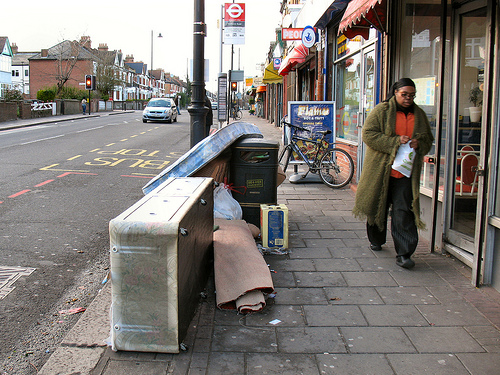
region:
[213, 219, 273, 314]
a rolled up piece of carpet on the sidewalk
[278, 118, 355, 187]
a blue adult bicycle with two tires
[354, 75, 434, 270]
a woman wearing a green coat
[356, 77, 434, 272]
a woman walking down the sidewalk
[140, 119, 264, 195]
an old mattress tossed out to the curb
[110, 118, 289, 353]
a pile of trash stacked on the sidewalk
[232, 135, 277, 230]
a green trash can that needs emptied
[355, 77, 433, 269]
a woman wearing an orange shirt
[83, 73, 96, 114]
a black stoplight with an orange light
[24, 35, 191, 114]
a long row of apartment buildings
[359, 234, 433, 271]
Woman wearing shoes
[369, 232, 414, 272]
Woman is wearing shoes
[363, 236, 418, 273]
Woman wearing black shoes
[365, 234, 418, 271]
Woman is wearing black shoes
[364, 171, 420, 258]
Woman wearing pants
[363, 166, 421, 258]
Woman is wearing pants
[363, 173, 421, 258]
Woman wearing black pants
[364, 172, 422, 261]
Woman is wearing black pants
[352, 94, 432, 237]
Woman wearing a green coat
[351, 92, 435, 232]
Woman is wearing a green coat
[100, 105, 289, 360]
several items are on the sidewalk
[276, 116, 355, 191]
a bicycle is behind the woman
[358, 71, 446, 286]
a woman walks down the sidewalk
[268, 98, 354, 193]
the bicycle is next to the sign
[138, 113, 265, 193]
a mattress lay on top of the pile of items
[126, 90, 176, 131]
a car is in the road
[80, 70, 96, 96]
a traffic light is on the left side of the road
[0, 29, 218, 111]
buildings go all the way down the road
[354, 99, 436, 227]
the woman wears a long green sweater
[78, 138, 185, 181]
the road says BUS STOP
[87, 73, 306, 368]
debris left on the street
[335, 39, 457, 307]
a pedestrian walking down the sidewalk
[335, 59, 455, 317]
a pedestrian walking down a footpath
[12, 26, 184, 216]
an approaching automobile going near a bus stop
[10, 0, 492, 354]
a city street with shops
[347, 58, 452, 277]
a person with a black scarf and orange top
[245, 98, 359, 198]
a bicycle parked on a footpath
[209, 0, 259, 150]
the sign for a bus stop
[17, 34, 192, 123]
a row of townhouses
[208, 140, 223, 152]
the mattress is blue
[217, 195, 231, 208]
the bag is white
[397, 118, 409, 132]
the shirt is orange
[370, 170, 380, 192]
the jacket is olive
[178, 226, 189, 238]
the wheels are black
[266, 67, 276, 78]
the awning is yellow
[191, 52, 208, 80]
the pole is black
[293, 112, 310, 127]
the sign is blue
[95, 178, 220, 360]
A Piece of furniture left out on the curb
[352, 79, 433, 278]
A person walking on the sidewalk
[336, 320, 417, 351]
dark block in the grey sidewalk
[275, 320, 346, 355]
dark block in the grey sidewalk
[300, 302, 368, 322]
dark block in the grey sidewalk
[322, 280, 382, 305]
dark block in the grey sidewalk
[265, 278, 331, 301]
dark block in the grey sidewalk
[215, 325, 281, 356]
dark block in the grey sidewalk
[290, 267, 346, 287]
dark block in the grey sidewalk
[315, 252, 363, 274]
dark block in the grey sidewalk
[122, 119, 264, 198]
old bed mattress on curb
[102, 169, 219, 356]
old set of box springs